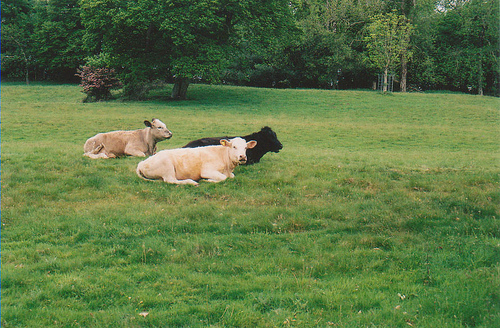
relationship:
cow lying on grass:
[85, 115, 174, 161] [1, 82, 500, 327]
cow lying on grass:
[138, 137, 258, 186] [1, 82, 500, 327]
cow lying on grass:
[182, 126, 283, 169] [1, 82, 500, 327]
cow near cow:
[138, 137, 258, 186] [182, 126, 283, 169]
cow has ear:
[85, 115, 174, 161] [144, 119, 153, 126]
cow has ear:
[138, 137, 258, 186] [220, 139, 230, 146]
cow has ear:
[138, 137, 258, 186] [247, 140, 257, 146]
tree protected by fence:
[365, 9, 416, 96] [378, 73, 394, 95]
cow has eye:
[85, 115, 174, 161] [157, 126, 161, 129]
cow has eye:
[138, 137, 258, 186] [235, 147, 238, 150]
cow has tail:
[85, 115, 174, 161] [82, 150, 113, 160]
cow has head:
[85, 115, 174, 161] [144, 119, 172, 140]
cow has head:
[182, 126, 283, 169] [258, 127, 283, 154]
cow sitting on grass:
[85, 115, 174, 161] [1, 82, 500, 327]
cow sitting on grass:
[138, 137, 258, 186] [1, 82, 500, 327]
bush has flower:
[76, 63, 122, 102] [112, 67, 117, 70]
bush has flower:
[76, 63, 122, 102] [88, 74, 89, 75]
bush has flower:
[76, 63, 122, 102] [114, 81, 116, 82]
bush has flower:
[76, 63, 122, 102] [88, 85, 95, 86]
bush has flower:
[76, 63, 122, 102] [96, 62, 101, 63]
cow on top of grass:
[138, 137, 258, 186] [1, 82, 500, 327]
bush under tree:
[76, 63, 122, 102] [80, 4, 164, 98]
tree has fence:
[365, 9, 416, 96] [378, 73, 394, 95]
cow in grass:
[85, 115, 174, 161] [1, 82, 500, 327]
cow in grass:
[138, 137, 258, 186] [1, 82, 500, 327]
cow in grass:
[182, 126, 283, 169] [1, 82, 500, 327]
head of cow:
[258, 127, 283, 154] [182, 126, 283, 169]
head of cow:
[144, 119, 172, 140] [85, 115, 174, 161]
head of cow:
[221, 136, 258, 167] [138, 137, 258, 186]